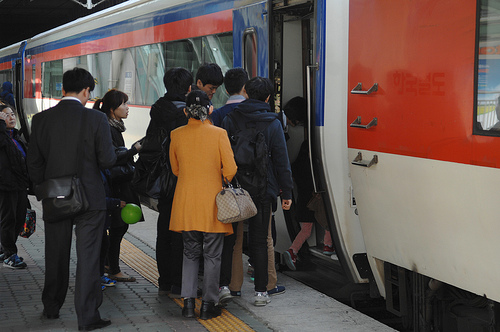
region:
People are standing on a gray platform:
[3, 62, 303, 324]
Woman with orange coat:
[168, 87, 248, 319]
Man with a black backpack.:
[220, 75, 293, 310]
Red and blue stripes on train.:
[5, 2, 242, 139]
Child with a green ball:
[101, 173, 143, 291]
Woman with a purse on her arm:
[168, 92, 257, 317]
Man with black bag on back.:
[25, 67, 123, 328]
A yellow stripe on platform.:
[118, 235, 251, 330]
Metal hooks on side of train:
[346, 76, 381, 178]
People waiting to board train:
[3, 61, 301, 328]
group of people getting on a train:
[9, 6, 429, 331]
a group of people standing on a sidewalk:
[28, 10, 335, 300]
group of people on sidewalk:
[25, 16, 382, 331]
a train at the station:
[2, 11, 499, 298]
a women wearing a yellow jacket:
[144, 70, 310, 309]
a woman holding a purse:
[159, 38, 276, 328]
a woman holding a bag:
[123, 62, 343, 296]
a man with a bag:
[27, 40, 159, 310]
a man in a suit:
[25, 32, 160, 324]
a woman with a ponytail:
[83, 46, 174, 285]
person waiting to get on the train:
[157, 83, 253, 327]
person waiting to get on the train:
[8, 63, 130, 330]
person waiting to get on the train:
[81, 78, 141, 293]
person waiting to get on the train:
[0, 91, 37, 278]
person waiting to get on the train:
[124, 60, 204, 312]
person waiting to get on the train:
[182, 55, 226, 127]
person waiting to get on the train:
[216, 61, 253, 123]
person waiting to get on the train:
[207, 75, 297, 315]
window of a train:
[460, 3, 499, 151]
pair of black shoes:
[171, 288, 238, 328]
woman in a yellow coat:
[167, 88, 235, 234]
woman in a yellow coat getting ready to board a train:
[163, 88, 240, 321]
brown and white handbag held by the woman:
[213, 171, 257, 224]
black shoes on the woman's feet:
[180, 292, 221, 320]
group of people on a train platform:
[3, 61, 295, 331]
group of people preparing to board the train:
[0, 56, 299, 328]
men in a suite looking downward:
[26, 64, 123, 330]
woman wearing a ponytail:
[88, 89, 131, 138]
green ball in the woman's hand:
[118, 201, 143, 224]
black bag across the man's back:
[31, 114, 88, 220]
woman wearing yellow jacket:
[174, 97, 240, 248]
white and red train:
[332, 1, 492, 296]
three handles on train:
[342, 75, 382, 177]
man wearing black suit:
[41, 66, 118, 269]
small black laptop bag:
[31, 168, 89, 230]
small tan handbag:
[212, 175, 258, 234]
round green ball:
[108, 194, 148, 226]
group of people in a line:
[1, 75, 296, 298]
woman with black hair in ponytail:
[93, 85, 125, 126]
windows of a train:
[38, 33, 245, 115]